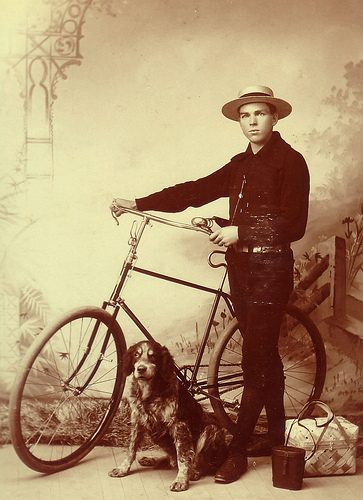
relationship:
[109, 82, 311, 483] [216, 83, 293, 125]
man wearing hat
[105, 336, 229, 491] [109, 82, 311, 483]
dog beside man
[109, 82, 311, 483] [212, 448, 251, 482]
man has foot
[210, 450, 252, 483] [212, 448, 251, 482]
shoe on foot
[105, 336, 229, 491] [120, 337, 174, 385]
dog has head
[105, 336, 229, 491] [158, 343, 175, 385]
dog has ear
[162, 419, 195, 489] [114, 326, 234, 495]
leg of dog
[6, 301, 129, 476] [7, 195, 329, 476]
bicycle wheel of bicycle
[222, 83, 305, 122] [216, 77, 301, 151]
hat on a man's head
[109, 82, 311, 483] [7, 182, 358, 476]
man posing with bicycle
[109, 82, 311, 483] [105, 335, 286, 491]
man posing with dog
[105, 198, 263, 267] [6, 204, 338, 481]
handlebars of a bicycle